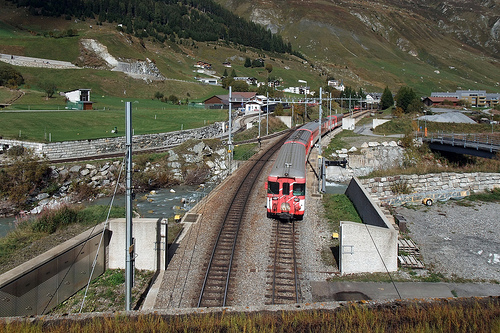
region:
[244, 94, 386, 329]
a train on the tracks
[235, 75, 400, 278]
an old train on the tracks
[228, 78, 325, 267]
a red train on the tracks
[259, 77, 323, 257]
a passenger train on the tracks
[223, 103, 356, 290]
an old red train on the tracks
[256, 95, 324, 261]
an old passenger train on the track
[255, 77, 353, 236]
an old passenger train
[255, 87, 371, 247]
an old red passenger train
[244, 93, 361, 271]
an old red passenger train on the tracksk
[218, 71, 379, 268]
a track with a train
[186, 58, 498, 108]
Small Country Side Village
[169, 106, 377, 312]
Old Rusted Train Tracks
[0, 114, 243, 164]
Cobblestone Wall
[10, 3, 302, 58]
Forest on the side of the mountain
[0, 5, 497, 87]
Bottom of the mountain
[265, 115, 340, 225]
Faded Red, White, and Grey Train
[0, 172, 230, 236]
Small flowing creek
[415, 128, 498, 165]
Short metal bridge over the creek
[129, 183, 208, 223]
Rushing water through the rocks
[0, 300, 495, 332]
Brown and light green grass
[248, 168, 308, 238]
The train is red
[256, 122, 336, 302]
The train is on tracks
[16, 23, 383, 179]
There is a large hill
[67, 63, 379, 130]
Buildings on the hill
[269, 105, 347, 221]
The train has many cars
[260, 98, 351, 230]
The train is moving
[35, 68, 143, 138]
The hillside is green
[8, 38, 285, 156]
The hillside is grassy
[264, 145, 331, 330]
The train goes under a bridge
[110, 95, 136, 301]
A large metal pole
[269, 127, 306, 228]
red train on the train track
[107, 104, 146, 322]
pole next to the train track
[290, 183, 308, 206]
window on the train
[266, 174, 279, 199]
window on the train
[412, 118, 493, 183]
bridge over a river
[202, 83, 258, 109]
red building near the tracks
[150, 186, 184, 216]
water in the river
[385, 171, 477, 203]
rock wall near the train tracks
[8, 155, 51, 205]
bushes near the river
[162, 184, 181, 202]
rock in the river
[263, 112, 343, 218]
The train is red.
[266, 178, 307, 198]
The train has three windows in the front.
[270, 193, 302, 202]
The train has two light in front.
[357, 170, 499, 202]
The wall is made of stone bricks.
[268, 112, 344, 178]
The train roof is silver.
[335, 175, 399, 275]
The wall is gray.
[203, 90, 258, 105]
The house is brown.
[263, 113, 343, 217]
The train has a white stripe on it's side.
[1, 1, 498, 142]
The mountain side is green.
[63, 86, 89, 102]
The side of the structure is white.